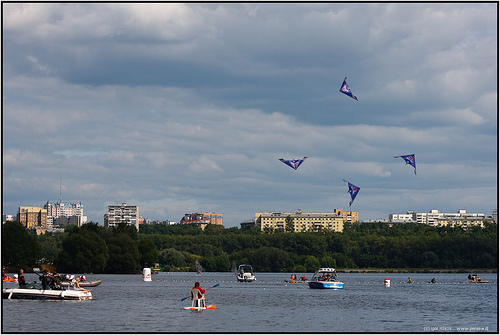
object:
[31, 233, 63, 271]
tree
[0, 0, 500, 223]
skies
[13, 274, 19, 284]
boat floating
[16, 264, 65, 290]
two people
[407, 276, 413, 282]
person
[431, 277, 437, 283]
person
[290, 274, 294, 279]
person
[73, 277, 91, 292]
person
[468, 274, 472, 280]
person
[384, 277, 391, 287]
barrier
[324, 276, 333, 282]
boater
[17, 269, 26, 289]
boater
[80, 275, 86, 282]
boater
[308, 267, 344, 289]
boat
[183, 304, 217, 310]
boat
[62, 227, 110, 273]
tree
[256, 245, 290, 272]
tree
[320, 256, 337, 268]
tree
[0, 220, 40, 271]
tree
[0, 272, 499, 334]
lake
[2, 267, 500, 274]
lake shore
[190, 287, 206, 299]
red shirt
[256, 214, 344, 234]
condos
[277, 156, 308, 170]
kite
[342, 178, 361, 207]
kite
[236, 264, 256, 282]
boat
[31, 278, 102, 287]
boat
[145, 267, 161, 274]
boat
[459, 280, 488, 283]
boat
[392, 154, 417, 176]
kites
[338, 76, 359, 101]
kites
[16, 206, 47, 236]
buildings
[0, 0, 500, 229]
clouds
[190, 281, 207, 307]
person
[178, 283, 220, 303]
oar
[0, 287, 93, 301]
boat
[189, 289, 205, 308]
chair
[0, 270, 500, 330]
water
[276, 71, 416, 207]
bunch